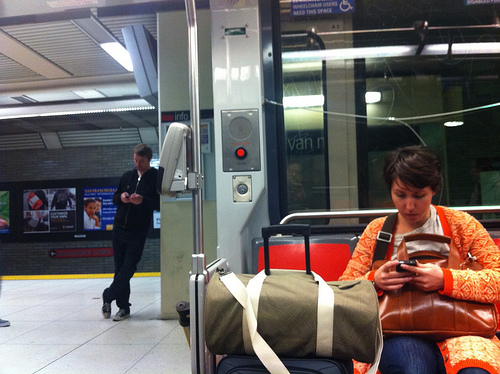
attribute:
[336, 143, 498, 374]
woman — sitting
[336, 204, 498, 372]
sweater — orange, long sleeve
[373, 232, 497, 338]
purse — brown, leather, large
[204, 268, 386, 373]
dufflebag — olive, green, white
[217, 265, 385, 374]
straps — white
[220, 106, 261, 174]
cover — grey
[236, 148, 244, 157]
button — red, small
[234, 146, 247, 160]
trim — black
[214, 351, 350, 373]
suitcase — blue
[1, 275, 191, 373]
ground — tiled, white, walkway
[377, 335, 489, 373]
jeans — blue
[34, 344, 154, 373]
tile — white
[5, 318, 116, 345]
tile — white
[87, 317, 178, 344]
tile — white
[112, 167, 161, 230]
jacket — black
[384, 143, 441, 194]
hair — dark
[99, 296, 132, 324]
sneakers — black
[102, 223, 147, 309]
pants — black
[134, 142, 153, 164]
hair — brown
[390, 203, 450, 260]
shirt — white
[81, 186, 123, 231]
billboard — blue, bright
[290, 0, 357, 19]
handicap sign — blue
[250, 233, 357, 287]
seat — orange, grey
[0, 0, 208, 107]
ceiling — metal